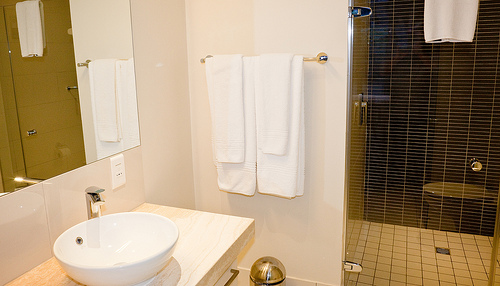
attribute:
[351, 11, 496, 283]
barrier — wire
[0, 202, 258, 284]
counter — wooden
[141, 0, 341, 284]
walls — tan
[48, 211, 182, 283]
sink — white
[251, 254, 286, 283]
can — gold colored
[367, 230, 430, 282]
tiles — white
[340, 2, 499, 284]
door — glass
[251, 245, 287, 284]
basker — gold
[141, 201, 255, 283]
counter — light marble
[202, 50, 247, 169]
towel — white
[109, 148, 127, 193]
plug — white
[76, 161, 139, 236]
water faucet — metal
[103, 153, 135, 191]
outlet — electric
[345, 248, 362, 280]
hinge door — silver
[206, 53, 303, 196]
towels — white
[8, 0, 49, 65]
towel — white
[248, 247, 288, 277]
container — metal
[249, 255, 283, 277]
top — reflective